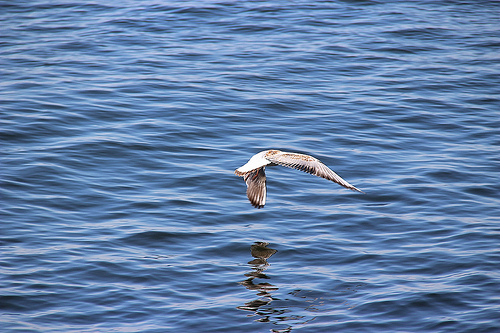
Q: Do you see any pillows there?
A: No, there are no pillows.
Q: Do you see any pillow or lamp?
A: No, there are no pillows or lamps.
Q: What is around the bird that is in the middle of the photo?
A: The water is around the bird.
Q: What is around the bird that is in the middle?
A: The water is around the bird.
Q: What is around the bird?
A: The water is around the bird.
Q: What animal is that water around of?
A: The water is around the bird.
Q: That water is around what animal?
A: The water is around the bird.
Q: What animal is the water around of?
A: The water is around the bird.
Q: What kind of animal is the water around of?
A: The water is around the bird.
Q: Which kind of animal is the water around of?
A: The water is around the bird.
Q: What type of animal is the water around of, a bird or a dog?
A: The water is around a bird.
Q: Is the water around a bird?
A: Yes, the water is around a bird.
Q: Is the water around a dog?
A: No, the water is around a bird.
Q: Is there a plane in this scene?
A: No, there are no airplanes.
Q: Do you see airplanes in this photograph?
A: No, there are no airplanes.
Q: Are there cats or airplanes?
A: No, there are no airplanes or cats.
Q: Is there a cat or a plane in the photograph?
A: No, there are no airplanes or cats.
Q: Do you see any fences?
A: No, there are no fences.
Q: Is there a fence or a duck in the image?
A: No, there are no fences or ducks.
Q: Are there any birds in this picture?
A: Yes, there is a bird.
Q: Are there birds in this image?
A: Yes, there is a bird.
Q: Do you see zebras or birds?
A: Yes, there is a bird.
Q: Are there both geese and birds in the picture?
A: No, there is a bird but no geese.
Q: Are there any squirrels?
A: No, there are no squirrels.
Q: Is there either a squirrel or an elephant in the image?
A: No, there are no squirrels or elephants.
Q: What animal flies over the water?
A: The bird flies over the water.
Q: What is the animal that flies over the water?
A: The animal is a bird.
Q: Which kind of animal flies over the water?
A: The animal is a bird.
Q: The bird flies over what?
A: The bird flies over the water.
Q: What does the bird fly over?
A: The bird flies over the water.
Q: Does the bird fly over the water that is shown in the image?
A: Yes, the bird flies over the water.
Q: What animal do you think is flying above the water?
A: The animal is a bird.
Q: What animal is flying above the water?
A: The animal is a bird.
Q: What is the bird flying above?
A: The bird is flying above the water.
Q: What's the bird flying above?
A: The bird is flying above the water.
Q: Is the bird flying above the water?
A: Yes, the bird is flying above the water.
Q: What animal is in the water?
A: The bird is in the water.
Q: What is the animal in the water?
A: The animal is a bird.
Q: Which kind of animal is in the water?
A: The animal is a bird.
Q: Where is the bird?
A: The bird is in the water.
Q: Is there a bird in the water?
A: Yes, there is a bird in the water.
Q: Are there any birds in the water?
A: Yes, there is a bird in the water.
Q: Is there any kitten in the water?
A: No, there is a bird in the water.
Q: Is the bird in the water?
A: Yes, the bird is in the water.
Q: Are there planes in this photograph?
A: No, there are no planes.